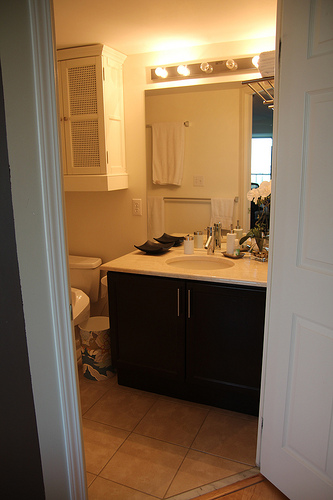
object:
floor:
[78, 372, 281, 499]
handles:
[177, 288, 190, 318]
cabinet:
[107, 268, 266, 417]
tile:
[100, 434, 183, 495]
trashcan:
[78, 315, 115, 382]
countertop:
[100, 233, 269, 287]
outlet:
[132, 198, 142, 216]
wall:
[59, 0, 152, 269]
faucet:
[204, 226, 215, 255]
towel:
[151, 123, 184, 188]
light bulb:
[252, 56, 261, 70]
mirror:
[249, 92, 273, 196]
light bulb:
[225, 60, 238, 71]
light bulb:
[200, 62, 214, 74]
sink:
[165, 255, 235, 271]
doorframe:
[255, 1, 330, 500]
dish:
[134, 240, 175, 256]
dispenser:
[227, 230, 238, 255]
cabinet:
[53, 39, 128, 193]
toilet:
[67, 257, 113, 381]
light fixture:
[154, 54, 259, 80]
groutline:
[163, 450, 224, 500]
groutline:
[88, 423, 175, 497]